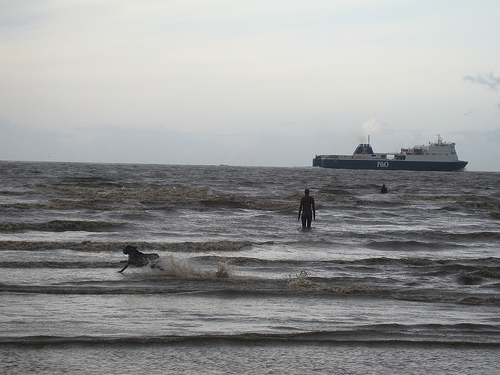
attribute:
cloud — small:
[459, 66, 499, 91]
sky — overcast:
[1, 1, 499, 170]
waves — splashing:
[157, 253, 242, 283]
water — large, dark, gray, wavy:
[3, 158, 498, 374]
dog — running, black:
[118, 244, 165, 274]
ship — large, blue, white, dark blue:
[312, 133, 469, 170]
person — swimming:
[379, 181, 390, 197]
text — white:
[375, 158, 391, 169]